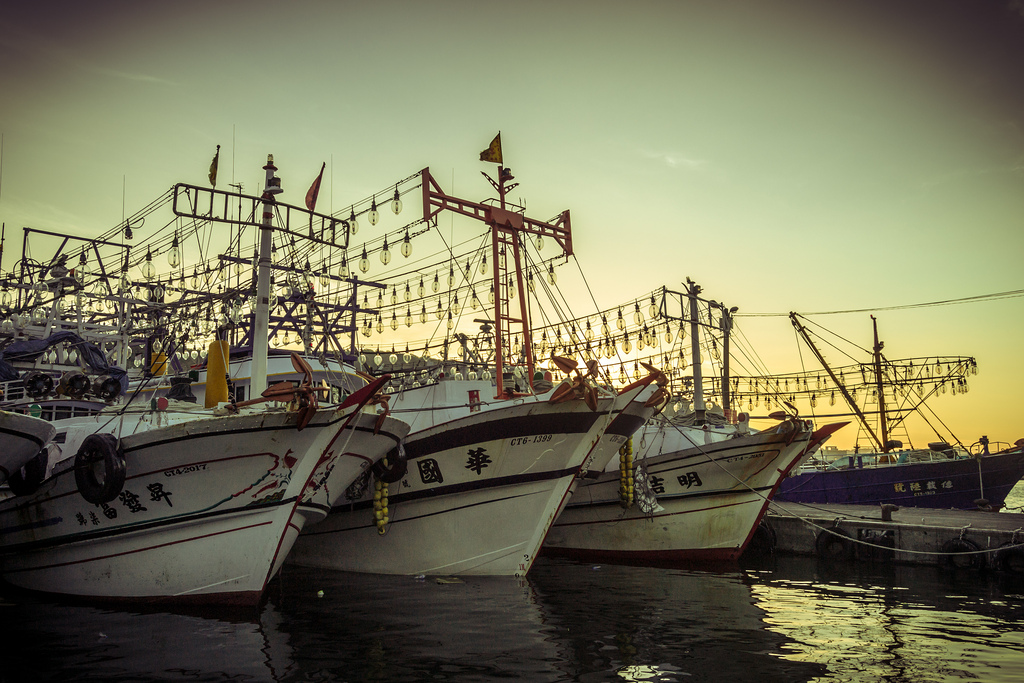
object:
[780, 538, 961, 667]
water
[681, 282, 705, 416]
pole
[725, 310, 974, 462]
cable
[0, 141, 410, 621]
boat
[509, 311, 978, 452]
sunset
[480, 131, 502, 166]
flag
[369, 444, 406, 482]
tire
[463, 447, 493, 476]
character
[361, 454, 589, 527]
stripe